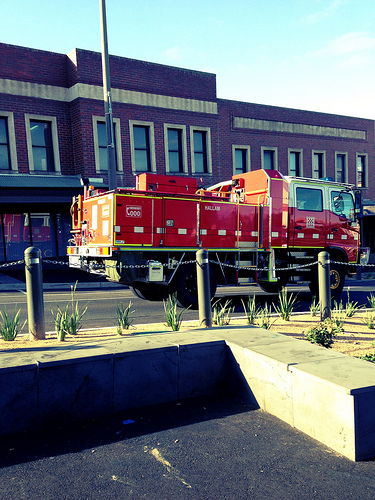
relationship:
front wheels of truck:
[256, 262, 344, 298] [66, 169, 361, 306]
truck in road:
[91, 149, 359, 312] [43, 287, 127, 318]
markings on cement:
[152, 438, 192, 492] [220, 431, 286, 476]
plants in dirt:
[148, 301, 333, 342] [256, 298, 372, 356]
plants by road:
[148, 301, 333, 342] [43, 276, 185, 323]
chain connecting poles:
[0, 258, 375, 270] [21, 247, 213, 334]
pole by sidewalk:
[23, 246, 45, 339] [3, 268, 126, 288]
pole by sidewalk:
[196, 249, 212, 328] [3, 268, 126, 288]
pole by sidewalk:
[317, 251, 330, 320] [3, 268, 126, 288]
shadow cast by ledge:
[0, 339, 261, 467] [0, 322, 375, 460]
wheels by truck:
[135, 265, 218, 308] [74, 178, 357, 306]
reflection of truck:
[4, 214, 46, 243] [130, 160, 337, 258]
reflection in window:
[4, 214, 46, 243] [4, 211, 51, 245]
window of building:
[29, 117, 53, 170] [2, 41, 373, 275]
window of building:
[0, 115, 10, 171] [2, 41, 373, 275]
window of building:
[96, 120, 117, 169] [2, 41, 373, 275]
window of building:
[133, 124, 151, 172] [2, 41, 373, 275]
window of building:
[166, 125, 184, 171] [2, 41, 373, 275]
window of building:
[193, 130, 208, 173] [2, 41, 373, 275]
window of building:
[233, 146, 244, 174] [2, 41, 373, 275]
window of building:
[263, 149, 274, 169] [2, 41, 373, 275]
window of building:
[290, 150, 298, 177] [2, 41, 373, 275]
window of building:
[312, 151, 323, 178] [2, 41, 373, 275]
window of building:
[337, 153, 343, 181] [2, 41, 373, 275]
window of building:
[356, 153, 365, 184] [2, 41, 373, 275]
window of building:
[27, 117, 54, 168] [193, 113, 311, 154]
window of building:
[314, 151, 323, 178] [2, 41, 373, 275]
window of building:
[335, 153, 344, 182] [2, 41, 373, 275]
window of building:
[358, 155, 366, 186] [2, 41, 373, 275]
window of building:
[335, 153, 344, 182] [5, 20, 370, 268]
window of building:
[353, 147, 371, 190] [2, 41, 373, 275]